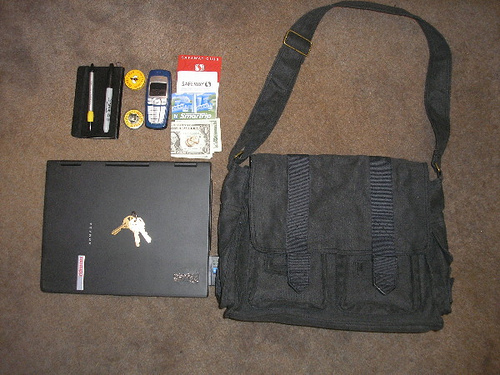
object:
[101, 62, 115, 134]
sharpie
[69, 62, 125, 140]
checkbook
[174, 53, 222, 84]
ticket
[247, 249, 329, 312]
pocket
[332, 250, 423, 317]
pocket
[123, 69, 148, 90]
circle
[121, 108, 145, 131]
circle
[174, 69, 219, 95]
receipt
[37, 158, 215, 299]
laptop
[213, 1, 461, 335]
black bag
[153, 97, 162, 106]
botton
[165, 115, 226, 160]
money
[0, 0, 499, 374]
carpet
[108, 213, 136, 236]
keys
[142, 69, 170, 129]
cell phone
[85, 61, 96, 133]
pen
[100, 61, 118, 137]
marker